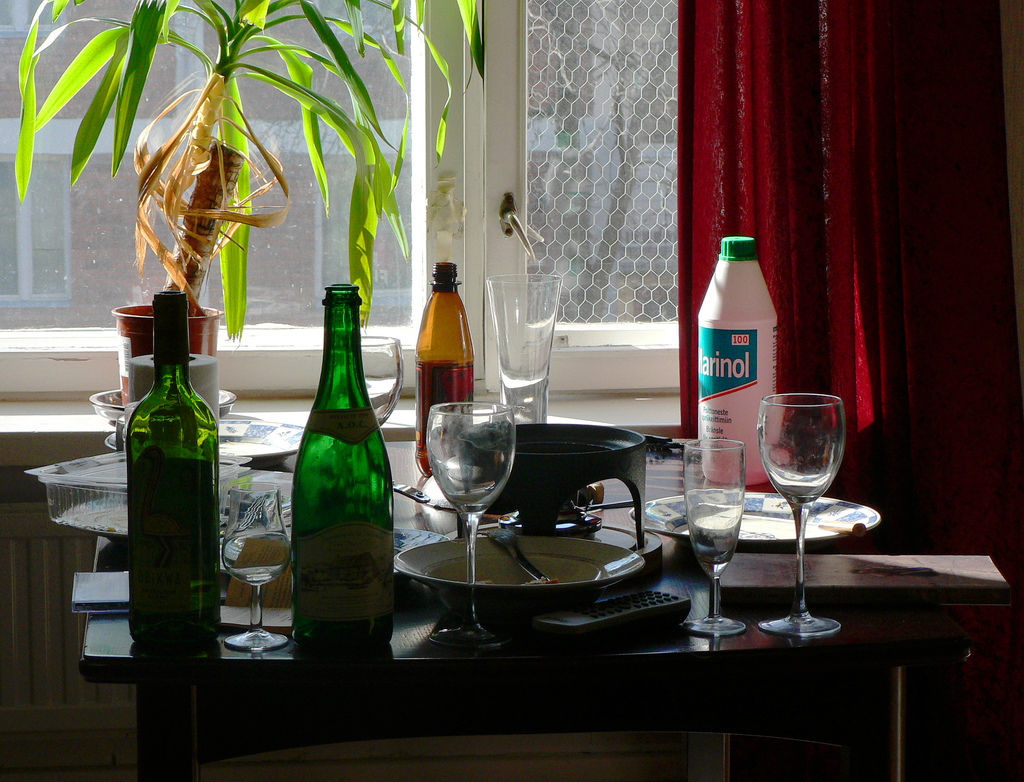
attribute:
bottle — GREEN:
[265, 273, 387, 695]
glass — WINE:
[416, 394, 505, 626]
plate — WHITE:
[751, 495, 780, 543]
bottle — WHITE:
[706, 243, 761, 486]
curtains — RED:
[759, 35, 881, 215]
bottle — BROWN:
[407, 269, 474, 410]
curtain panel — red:
[674, 0, 1010, 772]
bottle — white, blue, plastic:
[681, 229, 781, 491]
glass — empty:
[670, 432, 751, 640]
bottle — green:
[115, 283, 228, 655]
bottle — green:
[119, 289, 236, 663]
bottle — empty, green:
[279, 283, 400, 662]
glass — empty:
[415, 393, 521, 659]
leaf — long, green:
[101, 30, 160, 182]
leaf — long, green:
[41, 30, 122, 139]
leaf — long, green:
[296, 0, 398, 152]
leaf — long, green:
[238, 63, 386, 316]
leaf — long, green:
[7, 4, 49, 206]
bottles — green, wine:
[115, 276, 405, 678]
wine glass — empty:
[752, 384, 854, 640]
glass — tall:
[488, 264, 571, 422]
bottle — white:
[689, 229, 787, 491]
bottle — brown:
[413, 257, 480, 482]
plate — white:
[391, 520, 655, 644]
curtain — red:
[674, 0, 1016, 778]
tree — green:
[4, 4, 484, 309]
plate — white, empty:
[391, 520, 662, 629]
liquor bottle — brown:
[408, 250, 482, 480]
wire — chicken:
[529, 6, 676, 316]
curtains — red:
[674, 0, 1018, 778]